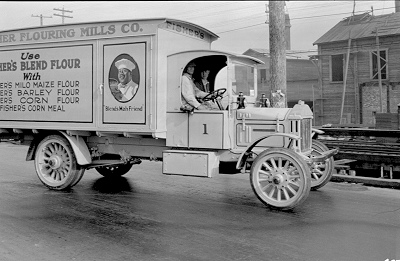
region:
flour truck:
[44, 41, 92, 120]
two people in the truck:
[189, 57, 225, 145]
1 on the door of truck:
[196, 120, 212, 136]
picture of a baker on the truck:
[101, 48, 141, 112]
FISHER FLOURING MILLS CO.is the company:
[0, 23, 151, 43]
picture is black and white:
[116, 20, 370, 220]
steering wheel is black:
[205, 86, 235, 111]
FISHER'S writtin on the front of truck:
[152, 12, 216, 41]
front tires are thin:
[240, 124, 380, 240]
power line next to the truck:
[220, 1, 325, 110]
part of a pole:
[264, 44, 280, 72]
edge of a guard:
[238, 150, 243, 179]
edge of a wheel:
[294, 162, 311, 191]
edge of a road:
[362, 173, 387, 186]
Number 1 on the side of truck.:
[191, 114, 221, 144]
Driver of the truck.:
[176, 59, 221, 113]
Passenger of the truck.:
[194, 60, 225, 108]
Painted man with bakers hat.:
[106, 48, 143, 103]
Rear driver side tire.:
[28, 131, 90, 193]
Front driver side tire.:
[246, 142, 312, 208]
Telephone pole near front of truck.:
[264, 13, 293, 110]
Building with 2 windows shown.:
[316, 11, 397, 128]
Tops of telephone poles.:
[27, 6, 75, 26]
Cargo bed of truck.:
[6, 22, 193, 138]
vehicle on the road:
[2, 14, 348, 217]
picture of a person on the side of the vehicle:
[105, 52, 147, 121]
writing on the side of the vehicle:
[2, 50, 96, 121]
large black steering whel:
[200, 80, 222, 106]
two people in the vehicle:
[183, 58, 233, 128]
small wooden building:
[299, 17, 397, 130]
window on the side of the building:
[323, 47, 346, 88]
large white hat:
[110, 52, 139, 73]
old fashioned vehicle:
[0, 16, 345, 226]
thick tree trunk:
[258, 1, 303, 131]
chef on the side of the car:
[94, 39, 160, 141]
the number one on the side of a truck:
[189, 118, 221, 150]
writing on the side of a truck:
[1, 50, 89, 131]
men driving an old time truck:
[168, 45, 261, 181]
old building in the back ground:
[300, 20, 397, 122]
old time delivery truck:
[1, 27, 343, 223]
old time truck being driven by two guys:
[130, 21, 288, 210]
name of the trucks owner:
[157, 15, 230, 48]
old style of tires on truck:
[22, 108, 112, 203]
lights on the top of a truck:
[227, 71, 264, 132]